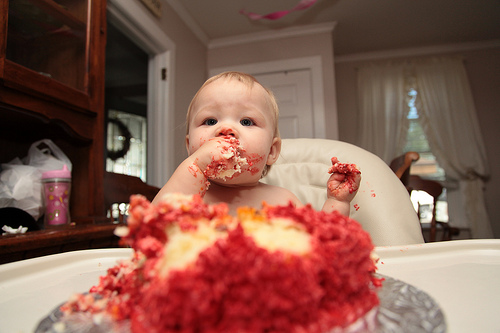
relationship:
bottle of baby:
[43, 161, 74, 237] [121, 34, 380, 221]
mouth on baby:
[211, 137, 243, 169] [128, 72, 359, 227]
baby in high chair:
[153, 72, 309, 214] [352, 153, 411, 241]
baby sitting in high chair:
[128, 72, 359, 227] [287, 126, 425, 248]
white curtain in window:
[355, 52, 498, 239] [403, 77, 445, 177]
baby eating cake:
[128, 72, 359, 227] [60, 191, 384, 331]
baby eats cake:
[128, 72, 359, 227] [76, 188, 398, 331]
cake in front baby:
[60, 191, 384, 331] [128, 72, 359, 227]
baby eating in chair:
[128, 72, 359, 227] [0, 136, 500, 332]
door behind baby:
[235, 68, 312, 138] [168, 76, 359, 213]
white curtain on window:
[410, 57, 497, 239] [357, 57, 474, 227]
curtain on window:
[356, 67, 411, 164] [357, 57, 474, 227]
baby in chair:
[128, 72, 359, 227] [0, 136, 500, 332]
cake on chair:
[108, 183, 384, 331] [7, 127, 498, 330]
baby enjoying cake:
[128, 72, 359, 227] [123, 201, 370, 326]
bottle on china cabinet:
[43, 162, 74, 232] [5, 9, 115, 238]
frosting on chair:
[113, 196, 381, 329] [0, 136, 500, 332]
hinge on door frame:
[162, 67, 167, 81] [108, 0, 177, 188]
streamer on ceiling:
[224, 0, 331, 38] [148, 0, 493, 101]